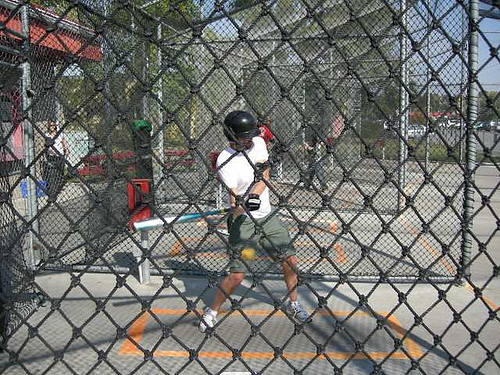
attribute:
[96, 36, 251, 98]
fence — black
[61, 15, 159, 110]
fence — black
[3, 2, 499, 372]
fence — black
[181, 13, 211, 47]
fence — black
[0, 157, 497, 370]
field — fenced